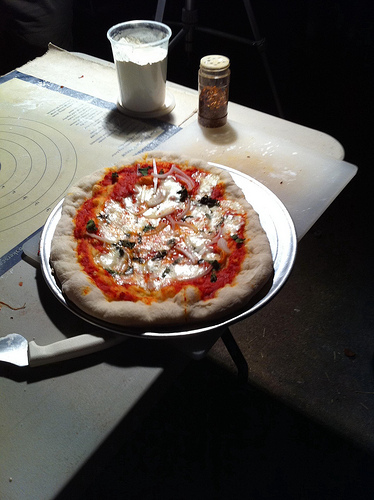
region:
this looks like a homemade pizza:
[50, 142, 276, 335]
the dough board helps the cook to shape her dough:
[0, 55, 188, 276]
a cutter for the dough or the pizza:
[1, 321, 145, 373]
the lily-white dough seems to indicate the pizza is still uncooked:
[46, 145, 278, 338]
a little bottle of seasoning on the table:
[194, 50, 232, 133]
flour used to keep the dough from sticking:
[103, 13, 178, 118]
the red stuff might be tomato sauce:
[70, 148, 253, 314]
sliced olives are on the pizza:
[174, 183, 225, 209]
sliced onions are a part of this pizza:
[149, 156, 198, 193]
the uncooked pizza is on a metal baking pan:
[34, 148, 300, 344]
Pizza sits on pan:
[45, 151, 276, 331]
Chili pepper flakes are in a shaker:
[195, 52, 229, 128]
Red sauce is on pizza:
[52, 149, 273, 330]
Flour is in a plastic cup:
[105, 18, 175, 115]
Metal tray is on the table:
[38, 148, 298, 338]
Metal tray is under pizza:
[38, 150, 299, 342]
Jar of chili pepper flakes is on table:
[194, 51, 228, 127]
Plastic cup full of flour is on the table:
[106, 18, 172, 113]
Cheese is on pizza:
[48, 150, 272, 326]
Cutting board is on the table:
[158, 113, 359, 246]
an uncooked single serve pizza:
[51, 149, 272, 318]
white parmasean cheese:
[90, 163, 223, 282]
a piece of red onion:
[158, 161, 196, 185]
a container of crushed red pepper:
[197, 52, 230, 127]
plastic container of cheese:
[106, 18, 171, 116]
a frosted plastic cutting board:
[22, 113, 358, 333]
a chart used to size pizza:
[1, 109, 77, 239]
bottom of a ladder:
[154, 0, 303, 115]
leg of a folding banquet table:
[213, 323, 256, 384]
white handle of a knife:
[0, 332, 108, 369]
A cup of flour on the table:
[104, 18, 177, 120]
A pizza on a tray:
[34, 144, 299, 343]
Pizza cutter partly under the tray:
[0, 328, 126, 370]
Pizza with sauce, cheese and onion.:
[49, 149, 275, 333]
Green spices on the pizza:
[81, 160, 247, 289]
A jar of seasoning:
[195, 53, 229, 131]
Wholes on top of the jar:
[198, 54, 231, 71]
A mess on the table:
[2, 280, 29, 324]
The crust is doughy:
[48, 150, 277, 333]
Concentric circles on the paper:
[0, 113, 82, 240]